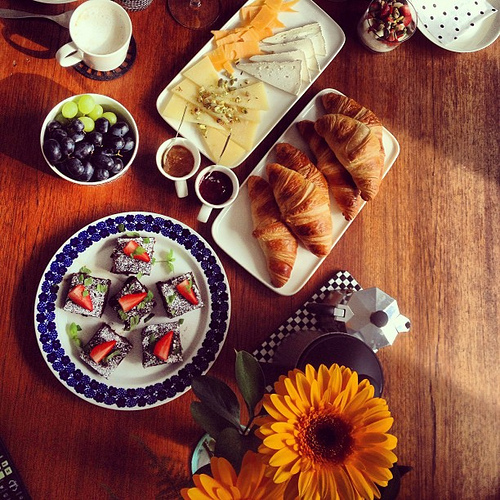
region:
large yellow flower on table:
[251, 347, 412, 495]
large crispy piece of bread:
[306, 102, 406, 211]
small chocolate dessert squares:
[49, 220, 214, 389]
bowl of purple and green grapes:
[33, 87, 147, 194]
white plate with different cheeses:
[148, 2, 352, 175]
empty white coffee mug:
[44, 5, 157, 88]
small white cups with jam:
[141, 120, 252, 237]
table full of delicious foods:
[5, 2, 495, 492]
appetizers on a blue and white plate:
[20, 207, 252, 416]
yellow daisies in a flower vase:
[136, 313, 430, 498]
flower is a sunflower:
[280, 377, 407, 485]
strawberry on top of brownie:
[60, 228, 211, 380]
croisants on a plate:
[255, 98, 416, 279]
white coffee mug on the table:
[47, 5, 139, 76]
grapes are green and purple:
[44, 84, 128, 189]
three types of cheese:
[149, 19, 354, 161]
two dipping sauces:
[161, 136, 252, 205]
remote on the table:
[1, 450, 32, 499]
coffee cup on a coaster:
[48, 15, 145, 82]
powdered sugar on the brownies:
[69, 221, 210, 390]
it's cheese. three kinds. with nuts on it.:
[153, 1, 345, 168]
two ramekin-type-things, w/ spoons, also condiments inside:
[146, 129, 244, 234]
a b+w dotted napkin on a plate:
[408, 0, 496, 47]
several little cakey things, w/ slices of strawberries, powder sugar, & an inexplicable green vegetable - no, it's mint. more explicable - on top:
[58, 233, 203, 381]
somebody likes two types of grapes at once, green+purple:
[39, 89, 139, 186]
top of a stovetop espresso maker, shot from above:
[314, 287, 423, 353]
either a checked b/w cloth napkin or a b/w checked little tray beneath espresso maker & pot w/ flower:
[243, 266, 382, 366]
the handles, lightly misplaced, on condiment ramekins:
[168, 177, 215, 229]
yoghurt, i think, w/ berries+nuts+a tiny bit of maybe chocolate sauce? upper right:
[346, 1, 417, 57]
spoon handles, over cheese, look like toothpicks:
[171, 101, 236, 166]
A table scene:
[8, 2, 493, 487]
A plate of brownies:
[32, 209, 224, 394]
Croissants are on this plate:
[251, 85, 397, 297]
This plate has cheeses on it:
[171, 1, 327, 145]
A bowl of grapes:
[39, 85, 142, 191]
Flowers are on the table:
[197, 366, 399, 498]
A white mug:
[54, 2, 148, 76]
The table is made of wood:
[406, 190, 482, 311]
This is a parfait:
[354, 2, 429, 53]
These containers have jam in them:
[151, 127, 241, 226]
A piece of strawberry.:
[70, 282, 97, 314]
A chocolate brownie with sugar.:
[64, 262, 112, 322]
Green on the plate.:
[152, 248, 184, 273]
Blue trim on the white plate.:
[44, 364, 199, 426]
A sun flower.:
[257, 361, 407, 498]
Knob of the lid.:
[369, 305, 393, 331]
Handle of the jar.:
[302, 292, 341, 323]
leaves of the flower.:
[229, 339, 267, 422]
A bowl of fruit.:
[34, 74, 141, 191]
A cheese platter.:
[163, 12, 320, 143]